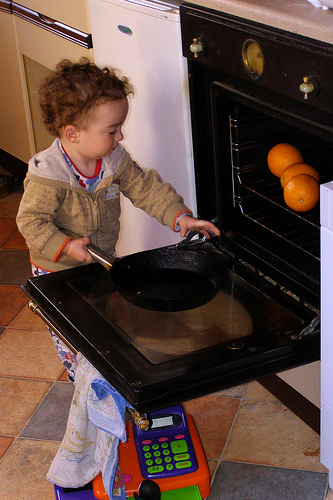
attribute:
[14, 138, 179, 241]
jacket — brown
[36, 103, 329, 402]
stove — open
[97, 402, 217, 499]
toy — cash register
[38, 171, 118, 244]
brown jacket — orange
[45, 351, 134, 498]
blanket — toddlers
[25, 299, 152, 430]
handle — door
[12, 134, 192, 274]
jacket — gray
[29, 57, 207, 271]
kid — small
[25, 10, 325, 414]
oven — black